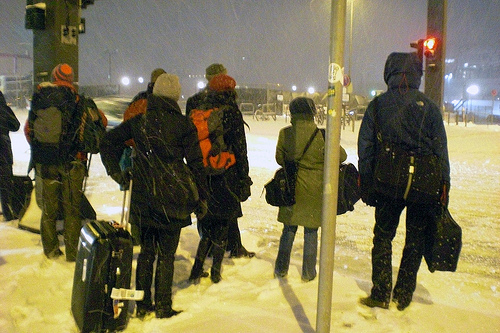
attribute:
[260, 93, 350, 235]
pedestrian — waiting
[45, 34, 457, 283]
jackets — blue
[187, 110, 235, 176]
backpack — red, black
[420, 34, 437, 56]
light — red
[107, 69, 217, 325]
woman — dressed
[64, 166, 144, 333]
suitcase — black, resting, large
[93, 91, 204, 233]
coat — green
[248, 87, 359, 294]
woman — dressed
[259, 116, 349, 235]
coat — green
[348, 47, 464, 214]
coat — black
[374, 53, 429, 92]
hood — built in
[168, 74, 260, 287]
woman — dressed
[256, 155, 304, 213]
handbag — black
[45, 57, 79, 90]
cap — orange, grey, striped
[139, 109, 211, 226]
handbag — black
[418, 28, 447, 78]
streetlight — red